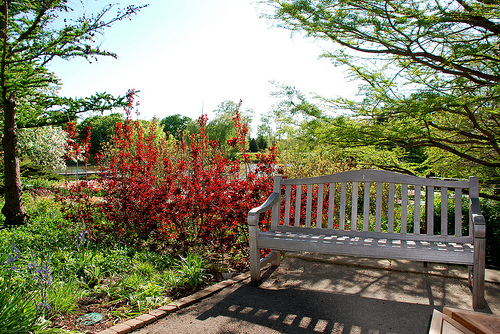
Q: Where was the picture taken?
A: It was taken at the patio.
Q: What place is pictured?
A: It is a patio.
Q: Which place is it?
A: It is a patio.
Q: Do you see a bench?
A: Yes, there is a bench.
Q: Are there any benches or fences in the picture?
A: Yes, there is a bench.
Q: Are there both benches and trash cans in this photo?
A: No, there is a bench but no trash cans.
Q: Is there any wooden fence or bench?
A: Yes, there is a wood bench.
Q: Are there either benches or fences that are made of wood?
A: Yes, the bench is made of wood.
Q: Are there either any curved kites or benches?
A: Yes, there is a curved bench.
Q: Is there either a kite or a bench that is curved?
A: Yes, the bench is curved.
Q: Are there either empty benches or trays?
A: Yes, there is an empty bench.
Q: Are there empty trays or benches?
A: Yes, there is an empty bench.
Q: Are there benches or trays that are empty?
A: Yes, the bench is empty.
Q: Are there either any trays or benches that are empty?
A: Yes, the bench is empty.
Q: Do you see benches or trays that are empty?
A: Yes, the bench is empty.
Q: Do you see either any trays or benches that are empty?
A: Yes, the bench is empty.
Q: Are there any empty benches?
A: Yes, there is an empty bench.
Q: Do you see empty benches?
A: Yes, there is an empty bench.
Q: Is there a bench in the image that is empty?
A: Yes, there is a bench that is empty.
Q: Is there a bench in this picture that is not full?
A: Yes, there is a empty bench.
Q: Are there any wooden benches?
A: Yes, there is a wood bench.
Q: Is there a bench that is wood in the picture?
A: Yes, there is a wood bench.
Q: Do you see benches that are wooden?
A: Yes, there is a bench that is wooden.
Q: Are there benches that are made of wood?
A: Yes, there is a bench that is made of wood.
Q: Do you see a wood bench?
A: Yes, there is a bench that is made of wood.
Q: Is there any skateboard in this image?
A: No, there are no skateboards.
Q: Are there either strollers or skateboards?
A: No, there are no skateboards or strollers.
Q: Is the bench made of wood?
A: Yes, the bench is made of wood.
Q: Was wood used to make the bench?
A: Yes, the bench is made of wood.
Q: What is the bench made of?
A: The bench is made of wood.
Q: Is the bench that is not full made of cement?
A: No, the bench is made of wood.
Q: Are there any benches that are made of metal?
A: No, there is a bench but it is made of wood.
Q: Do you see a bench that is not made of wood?
A: No, there is a bench but it is made of wood.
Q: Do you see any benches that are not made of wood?
A: No, there is a bench but it is made of wood.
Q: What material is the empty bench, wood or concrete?
A: The bench is made of wood.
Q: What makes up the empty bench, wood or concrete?
A: The bench is made of wood.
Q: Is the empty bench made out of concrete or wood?
A: The bench is made of wood.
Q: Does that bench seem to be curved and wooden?
A: Yes, the bench is curved and wooden.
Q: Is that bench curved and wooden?
A: Yes, the bench is curved and wooden.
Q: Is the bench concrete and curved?
A: No, the bench is curved but wooden.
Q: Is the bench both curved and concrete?
A: No, the bench is curved but wooden.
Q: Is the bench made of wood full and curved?
A: No, the bench is curved but empty.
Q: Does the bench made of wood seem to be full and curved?
A: No, the bench is curved but empty.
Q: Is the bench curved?
A: Yes, the bench is curved.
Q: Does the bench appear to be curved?
A: Yes, the bench is curved.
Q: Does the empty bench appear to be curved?
A: Yes, the bench is curved.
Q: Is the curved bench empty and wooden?
A: Yes, the bench is empty and wooden.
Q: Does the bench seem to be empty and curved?
A: Yes, the bench is empty and curved.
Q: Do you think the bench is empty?
A: Yes, the bench is empty.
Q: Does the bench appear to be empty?
A: Yes, the bench is empty.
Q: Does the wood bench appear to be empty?
A: Yes, the bench is empty.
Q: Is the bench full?
A: No, the bench is empty.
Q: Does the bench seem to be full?
A: No, the bench is empty.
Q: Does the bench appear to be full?
A: No, the bench is empty.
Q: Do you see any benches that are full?
A: No, there is a bench but it is empty.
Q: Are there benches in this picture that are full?
A: No, there is a bench but it is empty.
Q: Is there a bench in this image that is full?
A: No, there is a bench but it is empty.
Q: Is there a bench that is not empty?
A: No, there is a bench but it is empty.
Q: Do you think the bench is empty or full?
A: The bench is empty.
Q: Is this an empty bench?
A: Yes, this is an empty bench.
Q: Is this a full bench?
A: No, this is an empty bench.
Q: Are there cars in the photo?
A: No, there are no cars.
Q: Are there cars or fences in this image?
A: No, there are no cars or fences.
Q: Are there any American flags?
A: No, there are no American flags.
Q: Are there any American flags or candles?
A: No, there are no American flags or candles.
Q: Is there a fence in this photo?
A: No, there are no fences.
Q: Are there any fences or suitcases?
A: No, there are no fences or suitcases.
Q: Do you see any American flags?
A: No, there are no American flags.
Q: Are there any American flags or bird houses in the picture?
A: No, there are no American flags or bird houses.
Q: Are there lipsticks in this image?
A: No, there are no lipsticks.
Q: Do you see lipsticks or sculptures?
A: No, there are no lipsticks or sculptures.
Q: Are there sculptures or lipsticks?
A: No, there are no lipsticks or sculptures.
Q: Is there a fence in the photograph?
A: No, there are no fences.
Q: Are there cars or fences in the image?
A: No, there are no fences or cars.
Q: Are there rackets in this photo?
A: No, there are no rackets.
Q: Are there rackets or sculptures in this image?
A: No, there are no rackets or sculptures.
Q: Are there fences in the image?
A: No, there are no fences.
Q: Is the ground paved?
A: Yes, the ground is paved.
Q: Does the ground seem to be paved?
A: Yes, the ground is paved.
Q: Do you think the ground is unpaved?
A: No, the ground is paved.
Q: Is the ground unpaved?
A: No, the ground is paved.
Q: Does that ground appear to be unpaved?
A: No, the ground is paved.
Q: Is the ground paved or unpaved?
A: The ground is paved.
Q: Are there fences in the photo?
A: No, there are no fences.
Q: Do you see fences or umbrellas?
A: No, there are no fences or umbrellas.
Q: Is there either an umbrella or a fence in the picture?
A: No, there are no fences or umbrellas.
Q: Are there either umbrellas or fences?
A: No, there are no fences or umbrellas.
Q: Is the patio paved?
A: Yes, the patio is paved.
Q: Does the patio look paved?
A: Yes, the patio is paved.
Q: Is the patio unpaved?
A: No, the patio is paved.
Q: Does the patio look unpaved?
A: No, the patio is paved.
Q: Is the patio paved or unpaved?
A: The patio is paved.